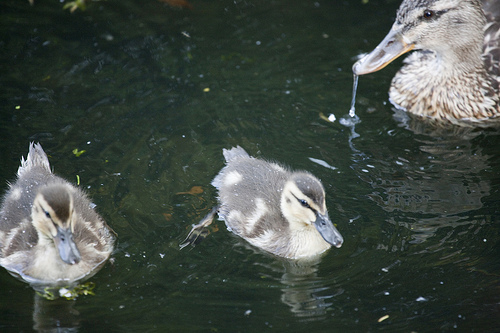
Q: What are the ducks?
A: Birds.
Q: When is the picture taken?
A: Daytime.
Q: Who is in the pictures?
A: Ducks.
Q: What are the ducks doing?
A: Swimming.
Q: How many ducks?
A: Three.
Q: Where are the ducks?
A: In water.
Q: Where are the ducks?
A: At a park.